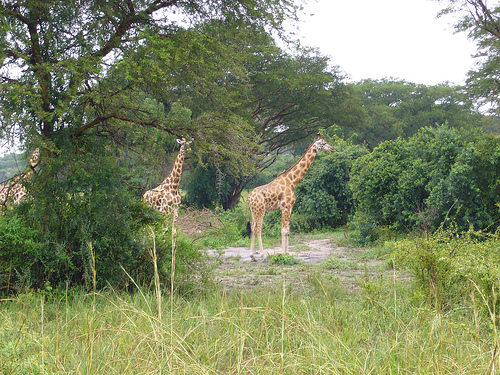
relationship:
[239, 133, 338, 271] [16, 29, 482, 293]
girafee standing in forrest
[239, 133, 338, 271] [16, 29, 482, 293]
girafee in forrest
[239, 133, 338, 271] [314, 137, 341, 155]
girafee big head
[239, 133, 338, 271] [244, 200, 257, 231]
girafee has tail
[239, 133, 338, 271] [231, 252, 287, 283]
girafee on ground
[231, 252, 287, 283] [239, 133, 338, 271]
ground below girafee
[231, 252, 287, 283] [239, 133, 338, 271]
ground near girafee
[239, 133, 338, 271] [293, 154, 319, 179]
girafee long neck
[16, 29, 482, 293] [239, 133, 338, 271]
forrest near girafee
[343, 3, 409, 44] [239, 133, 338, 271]
sky above girafee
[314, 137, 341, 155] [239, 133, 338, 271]
head of girafee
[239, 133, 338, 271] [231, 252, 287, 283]
girafee standing on ground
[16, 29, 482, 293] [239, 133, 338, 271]
forrest behind girafee